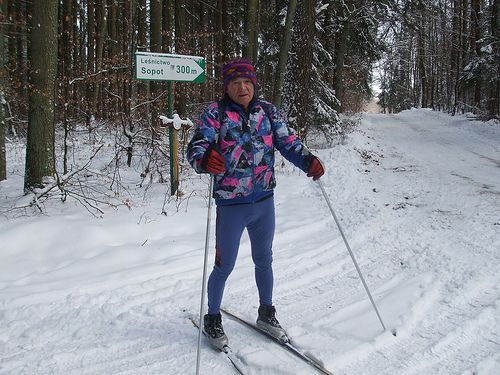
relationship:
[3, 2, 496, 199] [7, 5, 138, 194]
forest full of trees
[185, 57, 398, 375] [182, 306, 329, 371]
elderly skiier standing on skis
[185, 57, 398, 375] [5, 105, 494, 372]
elderly skiier standing on snow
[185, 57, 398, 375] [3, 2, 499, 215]
elderly skiier posing in front of forest